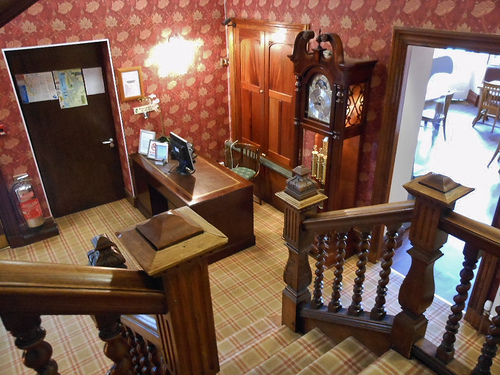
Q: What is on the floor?
A: Carpet.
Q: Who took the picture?
A: The photographer.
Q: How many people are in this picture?
A: None.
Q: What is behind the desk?
A: A chair.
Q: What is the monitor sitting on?
A: The desk.